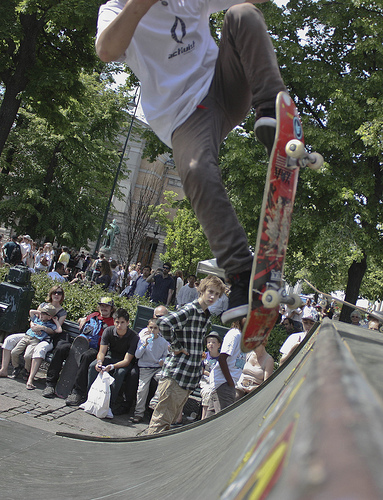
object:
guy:
[91, 0, 311, 366]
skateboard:
[236, 88, 325, 357]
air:
[1, 0, 381, 499]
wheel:
[284, 135, 308, 165]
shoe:
[251, 108, 278, 157]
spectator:
[0, 284, 69, 392]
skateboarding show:
[1, 1, 381, 500]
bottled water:
[147, 330, 156, 348]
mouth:
[148, 332, 156, 336]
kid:
[10, 301, 56, 382]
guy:
[54, 294, 115, 409]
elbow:
[92, 31, 128, 68]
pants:
[169, 2, 289, 274]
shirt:
[92, 1, 244, 148]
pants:
[206, 382, 235, 416]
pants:
[148, 374, 190, 438]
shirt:
[94, 324, 141, 361]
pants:
[45, 341, 98, 400]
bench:
[129, 301, 240, 403]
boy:
[146, 270, 229, 436]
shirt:
[155, 297, 214, 392]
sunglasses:
[50, 290, 63, 297]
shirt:
[81, 309, 115, 350]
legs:
[171, 135, 255, 319]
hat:
[35, 298, 60, 318]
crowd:
[0, 227, 274, 435]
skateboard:
[51, 332, 91, 402]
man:
[130, 299, 175, 427]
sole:
[253, 123, 279, 153]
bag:
[78, 369, 118, 420]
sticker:
[291, 114, 305, 139]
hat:
[204, 330, 223, 342]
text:
[166, 38, 197, 60]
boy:
[131, 314, 170, 424]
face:
[50, 288, 63, 303]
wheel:
[259, 285, 283, 315]